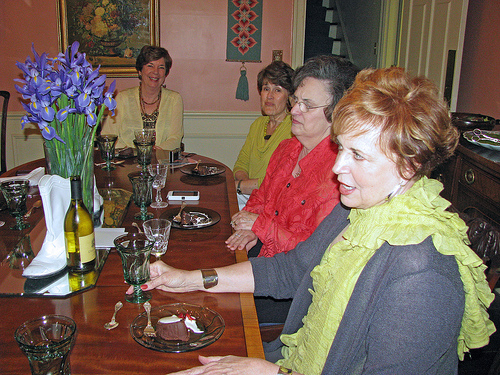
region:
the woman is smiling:
[135, 44, 171, 89]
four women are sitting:
[97, 44, 492, 374]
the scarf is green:
[276, 175, 495, 374]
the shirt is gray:
[248, 203, 464, 374]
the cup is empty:
[113, 232, 153, 302]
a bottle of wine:
[64, 175, 99, 290]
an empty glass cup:
[15, 315, 77, 373]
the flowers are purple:
[16, 43, 118, 140]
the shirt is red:
[241, 138, 339, 260]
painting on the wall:
[58, 1, 159, 76]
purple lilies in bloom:
[15, 44, 117, 139]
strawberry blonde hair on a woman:
[330, 69, 460, 181]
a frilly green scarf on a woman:
[278, 177, 498, 372]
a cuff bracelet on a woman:
[194, 264, 222, 291]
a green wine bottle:
[56, 174, 96, 275]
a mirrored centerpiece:
[1, 184, 131, 298]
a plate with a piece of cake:
[132, 299, 224, 358]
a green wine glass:
[115, 235, 155, 308]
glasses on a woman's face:
[285, 92, 332, 114]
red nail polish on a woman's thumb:
[139, 284, 147, 290]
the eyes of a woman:
[327, 139, 380, 166]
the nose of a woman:
[319, 152, 349, 173]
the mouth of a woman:
[333, 179, 363, 199]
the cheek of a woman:
[356, 166, 383, 190]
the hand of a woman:
[131, 263, 177, 298]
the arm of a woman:
[190, 242, 302, 294]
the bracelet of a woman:
[192, 265, 228, 294]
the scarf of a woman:
[336, 199, 477, 281]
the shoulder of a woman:
[386, 254, 473, 309]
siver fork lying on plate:
[135, 293, 162, 339]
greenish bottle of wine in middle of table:
[52, 164, 130, 316]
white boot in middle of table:
[33, 174, 79, 295]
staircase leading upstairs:
[313, 13, 363, 58]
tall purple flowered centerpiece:
[11, 44, 113, 219]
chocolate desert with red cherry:
[154, 306, 201, 340]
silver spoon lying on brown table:
[102, 289, 129, 354]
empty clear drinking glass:
[138, 219, 182, 254]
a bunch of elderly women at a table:
[227, 70, 476, 318]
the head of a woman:
[329, 81, 449, 211]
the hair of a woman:
[391, 127, 438, 168]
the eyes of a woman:
[326, 137, 372, 167]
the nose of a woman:
[322, 139, 350, 181]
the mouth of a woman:
[331, 177, 374, 201]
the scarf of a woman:
[341, 199, 488, 339]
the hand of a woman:
[123, 262, 185, 305]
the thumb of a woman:
[134, 276, 170, 292]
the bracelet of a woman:
[188, 254, 237, 302]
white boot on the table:
[23, 172, 85, 281]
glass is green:
[111, 232, 157, 305]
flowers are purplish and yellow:
[15, 38, 117, 221]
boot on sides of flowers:
[21, 159, 107, 282]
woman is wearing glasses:
[286, 89, 336, 116]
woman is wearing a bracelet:
[199, 264, 222, 291]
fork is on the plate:
[133, 291, 187, 355]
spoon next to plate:
[105, 297, 126, 331]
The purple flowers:
[12, 36, 126, 172]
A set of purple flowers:
[2, 32, 122, 157]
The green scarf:
[273, 185, 473, 373]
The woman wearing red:
[217, 50, 348, 261]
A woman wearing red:
[238, 54, 352, 253]